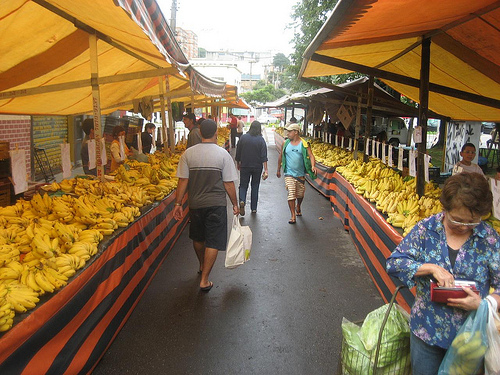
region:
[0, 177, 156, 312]
A large number of bananas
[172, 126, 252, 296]
A man carrying a bag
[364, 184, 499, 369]
A woman carrying multiple bags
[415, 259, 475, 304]
The woman examines her wallet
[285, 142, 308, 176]
The man is wearing a blue shirt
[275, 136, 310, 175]
The man is wearing a green jacket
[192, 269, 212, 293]
Sandals on the man's feet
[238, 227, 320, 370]
Cement under pedestrians feet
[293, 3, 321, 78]
Trees in the distance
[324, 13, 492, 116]
Orange and yellow awnings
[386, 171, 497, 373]
a woman holding a wallet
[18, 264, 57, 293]
a bunch of bananas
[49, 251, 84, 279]
a bunch of bananas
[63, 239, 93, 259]
a bunch of bananas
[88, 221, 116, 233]
a bunch of bananas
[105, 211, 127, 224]
a bunch of bananas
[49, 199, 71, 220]
a bunch of bananas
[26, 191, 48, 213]
a bunch of bananas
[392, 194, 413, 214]
a bunch of bananas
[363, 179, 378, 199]
a bunch of bananas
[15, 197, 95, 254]
the bananas on the left table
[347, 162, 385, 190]
bananas on the right table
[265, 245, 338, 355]
the black pavement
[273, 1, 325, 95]
the tall trees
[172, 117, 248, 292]
the man wearing gray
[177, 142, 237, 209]
the man's two toned gray shirt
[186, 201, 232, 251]
the man's dark colored pants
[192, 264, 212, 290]
the man's slippers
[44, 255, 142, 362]
the orange and black tablecloth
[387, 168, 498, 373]
the woman looking in her red wallet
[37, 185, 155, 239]
bananas are yellow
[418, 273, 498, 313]
woman looking in her wallet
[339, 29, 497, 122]
canopy is yellow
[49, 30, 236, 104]
canopies over the bananas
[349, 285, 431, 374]
shopping cart is full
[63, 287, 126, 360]
bottom of table has red and black stripe cover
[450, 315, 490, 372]
woman holding a bag of bananas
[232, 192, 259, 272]
man carrying a shopping bag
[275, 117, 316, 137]
man is wearing a ballcap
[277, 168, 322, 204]
man is wearing stripes shorts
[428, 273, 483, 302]
opened red wallet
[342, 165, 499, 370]
woman stopped checking her wallet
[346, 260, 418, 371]
a push basket with packages in it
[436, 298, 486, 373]
a woman holding a blue bag with bananas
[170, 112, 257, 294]
man is wearing shorts walking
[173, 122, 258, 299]
man carrying a white bags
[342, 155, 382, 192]
yellow bananas on a shelf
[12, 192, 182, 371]
red and black table cloth with bananas on top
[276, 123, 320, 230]
a man walking with a hat and blue shirt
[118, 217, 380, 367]
cement path inside produce stand